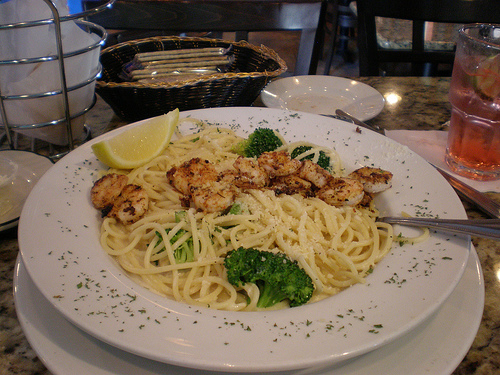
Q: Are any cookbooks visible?
A: No, there are no cookbooks.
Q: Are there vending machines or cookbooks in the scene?
A: No, there are no cookbooks or vending machines.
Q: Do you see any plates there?
A: Yes, there is a plate.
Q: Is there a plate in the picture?
A: Yes, there is a plate.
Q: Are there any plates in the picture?
A: Yes, there is a plate.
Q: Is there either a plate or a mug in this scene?
A: Yes, there is a plate.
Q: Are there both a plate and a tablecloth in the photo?
A: No, there is a plate but no tablecloths.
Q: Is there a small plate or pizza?
A: Yes, there is a small plate.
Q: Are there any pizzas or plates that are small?
A: Yes, the plate is small.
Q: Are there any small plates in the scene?
A: Yes, there is a small plate.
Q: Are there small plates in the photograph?
A: Yes, there is a small plate.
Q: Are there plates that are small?
A: Yes, there is a plate that is small.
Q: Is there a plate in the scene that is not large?
A: Yes, there is a small plate.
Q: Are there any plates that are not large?
A: Yes, there is a small plate.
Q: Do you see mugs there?
A: No, there are no mugs.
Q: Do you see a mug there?
A: No, there are no mugs.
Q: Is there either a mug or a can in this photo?
A: No, there are no mugs or cans.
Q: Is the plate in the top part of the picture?
A: Yes, the plate is in the top of the image.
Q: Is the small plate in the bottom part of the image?
A: No, the plate is in the top of the image.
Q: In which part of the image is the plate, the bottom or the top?
A: The plate is in the top of the image.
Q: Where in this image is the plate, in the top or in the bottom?
A: The plate is in the top of the image.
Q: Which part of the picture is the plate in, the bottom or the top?
A: The plate is in the top of the image.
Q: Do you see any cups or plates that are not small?
A: No, there is a plate but it is small.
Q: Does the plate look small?
A: Yes, the plate is small.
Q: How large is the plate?
A: The plate is small.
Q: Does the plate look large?
A: No, the plate is small.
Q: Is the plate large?
A: No, the plate is small.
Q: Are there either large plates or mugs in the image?
A: No, there is a plate but it is small.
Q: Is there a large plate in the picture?
A: No, there is a plate but it is small.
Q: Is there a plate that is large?
A: No, there is a plate but it is small.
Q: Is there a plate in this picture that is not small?
A: No, there is a plate but it is small.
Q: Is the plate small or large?
A: The plate is small.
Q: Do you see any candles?
A: No, there are no candles.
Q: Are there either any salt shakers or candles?
A: No, there are no candles or salt shakers.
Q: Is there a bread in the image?
A: No, there is no breads.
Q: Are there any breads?
A: No, there are no breads.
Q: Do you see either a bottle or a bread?
A: No, there are no breads or bottles.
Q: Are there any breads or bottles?
A: No, there are no breads or bottles.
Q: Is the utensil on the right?
A: Yes, the utensil is on the right of the image.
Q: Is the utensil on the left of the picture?
A: No, the utensil is on the right of the image.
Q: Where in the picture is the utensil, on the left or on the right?
A: The utensil is on the right of the image.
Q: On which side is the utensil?
A: The utensil is on the right of the image.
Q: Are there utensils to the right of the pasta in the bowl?
A: Yes, there is a utensil to the right of the pasta.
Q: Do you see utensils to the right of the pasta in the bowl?
A: Yes, there is a utensil to the right of the pasta.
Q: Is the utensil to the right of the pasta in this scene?
A: Yes, the utensil is to the right of the pasta.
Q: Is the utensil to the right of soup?
A: No, the utensil is to the right of the pasta.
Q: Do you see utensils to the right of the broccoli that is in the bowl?
A: Yes, there is a utensil to the right of the broccoli.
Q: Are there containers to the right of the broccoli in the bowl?
A: No, there is a utensil to the right of the broccoli.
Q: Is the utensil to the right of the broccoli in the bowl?
A: Yes, the utensil is to the right of the broccoli.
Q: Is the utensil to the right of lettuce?
A: No, the utensil is to the right of the broccoli.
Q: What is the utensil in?
A: The utensil is in the bowl.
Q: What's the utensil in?
A: The utensil is in the bowl.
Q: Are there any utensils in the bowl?
A: Yes, there is a utensil in the bowl.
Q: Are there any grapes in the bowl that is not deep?
A: No, there is a utensil in the bowl.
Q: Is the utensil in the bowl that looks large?
A: Yes, the utensil is in the bowl.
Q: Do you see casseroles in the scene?
A: No, there are no casseroles.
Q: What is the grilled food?
A: The food is shrimp.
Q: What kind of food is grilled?
A: The food is shrimp.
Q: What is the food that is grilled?
A: The food is shrimp.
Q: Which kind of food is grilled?
A: The food is shrimp.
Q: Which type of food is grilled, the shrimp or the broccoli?
A: The shrimp is grilled.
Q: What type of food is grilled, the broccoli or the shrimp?
A: The shrimp is grilled.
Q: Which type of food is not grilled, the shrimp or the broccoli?
A: The broccoli is not grilled.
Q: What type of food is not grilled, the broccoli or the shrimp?
A: The broccoli is not grilled.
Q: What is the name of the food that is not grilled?
A: The food is broccoli.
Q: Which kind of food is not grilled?
A: The food is broccoli.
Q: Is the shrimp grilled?
A: Yes, the shrimp is grilled.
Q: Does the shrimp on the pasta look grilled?
A: Yes, the shrimp is grilled.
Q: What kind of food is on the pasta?
A: The food is shrimp.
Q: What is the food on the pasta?
A: The food is shrimp.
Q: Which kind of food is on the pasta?
A: The food is shrimp.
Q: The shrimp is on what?
A: The shrimp is on the pasta.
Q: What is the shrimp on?
A: The shrimp is on the pasta.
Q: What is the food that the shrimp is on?
A: The food is pasta.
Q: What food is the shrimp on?
A: The shrimp is on the pasta.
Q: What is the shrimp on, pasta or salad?
A: The shrimp is on pasta.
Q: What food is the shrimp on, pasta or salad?
A: The shrimp is on pasta.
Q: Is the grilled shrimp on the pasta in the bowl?
A: Yes, the shrimp is on the pasta.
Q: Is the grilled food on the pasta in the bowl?
A: Yes, the shrimp is on the pasta.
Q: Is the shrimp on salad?
A: No, the shrimp is on the pasta.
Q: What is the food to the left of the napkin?
A: The food is shrimp.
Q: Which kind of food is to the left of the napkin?
A: The food is shrimp.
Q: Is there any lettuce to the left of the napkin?
A: No, there is shrimp to the left of the napkin.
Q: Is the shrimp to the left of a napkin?
A: Yes, the shrimp is to the left of a napkin.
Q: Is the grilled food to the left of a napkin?
A: Yes, the shrimp is to the left of a napkin.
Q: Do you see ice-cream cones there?
A: No, there are no ice-cream cones.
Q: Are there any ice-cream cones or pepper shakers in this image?
A: No, there are no ice-cream cones or pepper shakers.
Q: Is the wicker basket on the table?
A: Yes, the basket is on the table.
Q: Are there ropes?
A: No, there are no ropes.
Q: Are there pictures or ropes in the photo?
A: No, there are no ropes or pictures.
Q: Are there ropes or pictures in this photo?
A: No, there are no ropes or pictures.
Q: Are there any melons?
A: No, there are no melons.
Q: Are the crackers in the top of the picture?
A: Yes, the crackers are in the top of the image.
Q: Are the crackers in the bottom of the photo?
A: No, the crackers are in the top of the image.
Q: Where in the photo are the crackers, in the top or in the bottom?
A: The crackers are in the top of the image.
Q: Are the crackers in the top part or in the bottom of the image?
A: The crackers are in the top of the image.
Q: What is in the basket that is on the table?
A: The crackers are in the basket.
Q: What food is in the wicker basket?
A: The food is crackers.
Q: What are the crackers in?
A: The crackers are in the basket.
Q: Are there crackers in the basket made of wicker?
A: Yes, there are crackers in the basket.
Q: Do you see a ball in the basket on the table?
A: No, there are crackers in the basket.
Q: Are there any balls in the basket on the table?
A: No, there are crackers in the basket.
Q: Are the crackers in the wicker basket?
A: Yes, the crackers are in the basket.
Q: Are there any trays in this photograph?
A: No, there are no trays.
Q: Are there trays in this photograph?
A: No, there are no trays.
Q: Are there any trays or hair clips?
A: No, there are no trays or hair clips.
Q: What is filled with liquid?
A: The glass is filled with liquid.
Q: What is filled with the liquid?
A: The glass is filled with liquid.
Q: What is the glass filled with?
A: The glass is filled with liquid.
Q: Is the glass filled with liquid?
A: Yes, the glass is filled with liquid.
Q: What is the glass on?
A: The glass is on the table.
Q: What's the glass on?
A: The glass is on the table.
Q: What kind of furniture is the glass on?
A: The glass is on the table.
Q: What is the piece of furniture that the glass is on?
A: The piece of furniture is a table.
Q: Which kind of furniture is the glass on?
A: The glass is on the table.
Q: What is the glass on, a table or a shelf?
A: The glass is on a table.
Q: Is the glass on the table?
A: Yes, the glass is on the table.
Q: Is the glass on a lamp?
A: No, the glass is on the table.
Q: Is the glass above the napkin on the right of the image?
A: Yes, the glass is above the napkin.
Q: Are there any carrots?
A: No, there are no carrots.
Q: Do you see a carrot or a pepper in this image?
A: No, there are no carrots or peppers.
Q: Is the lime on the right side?
A: Yes, the lime is on the right of the image.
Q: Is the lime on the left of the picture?
A: No, the lime is on the right of the image.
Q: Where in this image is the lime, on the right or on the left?
A: The lime is on the right of the image.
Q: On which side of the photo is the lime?
A: The lime is on the right of the image.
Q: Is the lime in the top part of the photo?
A: Yes, the lime is in the top of the image.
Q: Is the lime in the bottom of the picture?
A: No, the lime is in the top of the image.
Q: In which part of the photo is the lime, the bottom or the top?
A: The lime is in the top of the image.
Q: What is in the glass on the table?
A: The lime is in the glass.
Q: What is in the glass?
A: The lime is in the glass.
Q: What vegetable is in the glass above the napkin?
A: The vegetable is a lime.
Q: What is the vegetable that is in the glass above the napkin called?
A: The vegetable is a lime.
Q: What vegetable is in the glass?
A: The vegetable is a lime.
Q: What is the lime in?
A: The lime is in the glass.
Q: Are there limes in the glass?
A: Yes, there is a lime in the glass.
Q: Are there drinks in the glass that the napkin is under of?
A: No, there is a lime in the glass.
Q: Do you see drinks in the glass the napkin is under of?
A: No, there is a lime in the glass.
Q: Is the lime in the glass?
A: Yes, the lime is in the glass.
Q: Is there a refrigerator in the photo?
A: No, there are no refrigerators.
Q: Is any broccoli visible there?
A: Yes, there is broccoli.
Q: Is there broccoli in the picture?
A: Yes, there is broccoli.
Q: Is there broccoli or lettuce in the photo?
A: Yes, there is broccoli.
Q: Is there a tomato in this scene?
A: No, there are no tomatoes.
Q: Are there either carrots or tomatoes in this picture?
A: No, there are no tomatoes or carrots.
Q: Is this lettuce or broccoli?
A: This is broccoli.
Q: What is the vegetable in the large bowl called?
A: The vegetable is broccoli.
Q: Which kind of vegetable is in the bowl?
A: The vegetable is broccoli.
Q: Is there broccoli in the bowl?
A: Yes, there is broccoli in the bowl.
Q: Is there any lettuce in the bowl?
A: No, there is broccoli in the bowl.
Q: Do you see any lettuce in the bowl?
A: No, there is broccoli in the bowl.